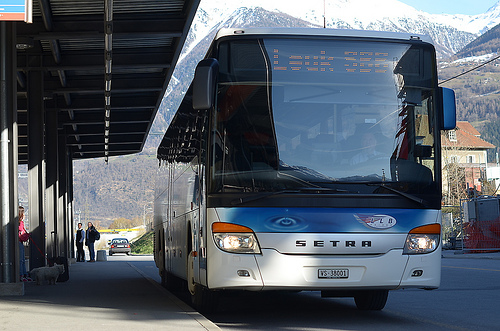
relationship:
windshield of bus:
[200, 31, 417, 183] [146, 14, 480, 310]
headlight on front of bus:
[210, 230, 263, 253] [146, 14, 480, 310]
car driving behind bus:
[106, 237, 131, 255] [146, 14, 480, 310]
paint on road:
[440, 261, 498, 275] [446, 257, 498, 315]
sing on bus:
[268, 42, 395, 78] [146, 14, 480, 310]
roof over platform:
[15, 2, 200, 159] [3, 248, 158, 327]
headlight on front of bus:
[401, 233, 441, 255] [146, 14, 480, 310]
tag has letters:
[306, 259, 358, 279] [320, 269, 328, 277]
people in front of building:
[85, 222, 100, 263] [1, 0, 200, 329]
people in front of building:
[76, 222, 86, 261] [1, 0, 200, 329]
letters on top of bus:
[268, 47, 390, 79] [152, 27, 456, 312]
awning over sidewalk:
[35, 2, 201, 161] [0, 257, 225, 328]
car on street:
[88, 215, 144, 272] [94, 225, 162, 282]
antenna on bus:
[319, 0, 329, 30] [152, 29, 446, 297]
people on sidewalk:
[85, 222, 100, 263] [0, 257, 225, 328]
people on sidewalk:
[76, 222, 86, 261] [0, 257, 225, 328]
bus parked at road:
[159, 53, 474, 321] [115, 249, 498, 330]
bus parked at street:
[152, 27, 456, 312] [108, 247, 498, 330]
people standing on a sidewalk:
[85, 222, 100, 263] [1, 250, 223, 329]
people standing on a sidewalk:
[76, 222, 86, 261] [1, 250, 223, 329]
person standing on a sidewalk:
[13, 200, 33, 282] [1, 250, 223, 329]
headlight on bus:
[212, 232, 262, 254] [126, 50, 456, 300]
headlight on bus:
[401, 233, 441, 255] [126, 50, 456, 300]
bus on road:
[152, 27, 456, 312] [115, 249, 498, 330]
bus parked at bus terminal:
[152, 27, 456, 312] [1, 0, 199, 330]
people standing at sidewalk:
[76, 214, 101, 256] [83, 240, 178, 329]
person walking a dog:
[13, 200, 33, 282] [27, 259, 66, 290]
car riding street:
[106, 237, 131, 255] [108, 247, 498, 330]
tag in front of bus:
[318, 268, 350, 279] [152, 27, 456, 312]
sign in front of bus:
[250, 31, 422, 88] [152, 27, 456, 312]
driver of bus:
[346, 127, 398, 176] [146, 14, 480, 310]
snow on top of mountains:
[334, 5, 375, 30] [321, 1, 417, 31]